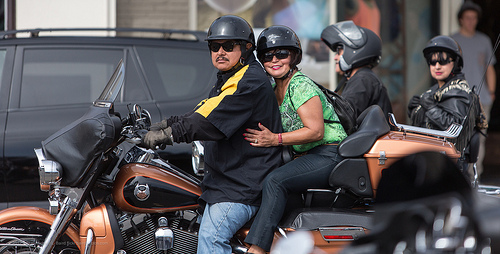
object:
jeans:
[253, 141, 344, 250]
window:
[18, 43, 128, 111]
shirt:
[170, 61, 282, 207]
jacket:
[408, 73, 484, 161]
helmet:
[424, 33, 464, 65]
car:
[0, 26, 224, 253]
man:
[320, 19, 393, 131]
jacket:
[336, 67, 396, 139]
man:
[140, 14, 281, 245]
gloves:
[144, 128, 172, 151]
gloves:
[150, 120, 168, 130]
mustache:
[215, 55, 230, 62]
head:
[205, 14, 255, 70]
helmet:
[203, 13, 258, 45]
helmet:
[320, 21, 384, 71]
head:
[332, 27, 382, 76]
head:
[426, 37, 461, 81]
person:
[406, 32, 483, 164]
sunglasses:
[424, 54, 459, 65]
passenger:
[237, 23, 358, 253]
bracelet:
[278, 133, 283, 146]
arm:
[282, 79, 325, 148]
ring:
[253, 137, 262, 143]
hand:
[242, 123, 277, 148]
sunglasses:
[206, 40, 240, 53]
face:
[208, 38, 248, 72]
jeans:
[199, 202, 256, 253]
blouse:
[272, 71, 348, 153]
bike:
[0, 101, 499, 252]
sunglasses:
[259, 45, 296, 62]